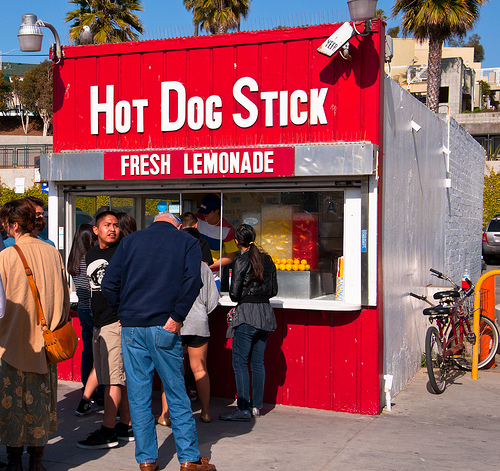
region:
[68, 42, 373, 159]
name of the resturant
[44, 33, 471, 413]
a mobile restaurant on road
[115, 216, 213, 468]
a tall person standing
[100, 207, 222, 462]
a tall person holding his hands on back pocket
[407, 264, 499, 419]
a nice by cycle parked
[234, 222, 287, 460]
a young girl standing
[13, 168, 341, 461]
a group of people standing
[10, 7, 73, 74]
a small top light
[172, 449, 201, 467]
shoe of the person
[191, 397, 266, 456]
shadow of the person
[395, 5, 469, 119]
tall green palm tree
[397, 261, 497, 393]
red bicycle built for two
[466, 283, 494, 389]
yellow pole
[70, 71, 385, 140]
hot dog stick sign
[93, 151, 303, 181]
red and white fresh lemonade sign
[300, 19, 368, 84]
security camera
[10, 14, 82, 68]
light fixture on building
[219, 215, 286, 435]
woman with a ponytail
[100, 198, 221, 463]
man in a dark blue jacket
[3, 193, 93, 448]
woman wearing a shoulder bag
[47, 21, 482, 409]
a take out restaurant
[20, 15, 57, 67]
an overhead light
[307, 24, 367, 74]
a white security camera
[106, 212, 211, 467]
a man reaching into pocket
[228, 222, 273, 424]
a woman standing on sidewalk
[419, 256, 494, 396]
a parked red bicycle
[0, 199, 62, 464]
a woman standing on sidewalk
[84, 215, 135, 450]
a man standing on sidewalk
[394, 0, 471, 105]
a large palm tree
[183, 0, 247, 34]
a large palm tree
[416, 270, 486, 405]
two person bike next to building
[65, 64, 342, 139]
name on top of building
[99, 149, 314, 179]
sign hanging on the building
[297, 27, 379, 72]
security camera on building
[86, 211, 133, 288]
boy looking at others in line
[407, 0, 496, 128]
palm tree behind building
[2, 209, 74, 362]
lady with bun in hair and satchel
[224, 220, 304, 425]
girl with ponytail and leather jacket on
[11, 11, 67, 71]
street light hanging up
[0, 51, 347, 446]
people in line for hot dog stand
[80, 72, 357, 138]
large white sign on the building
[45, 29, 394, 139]
red color on front of stand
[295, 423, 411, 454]
gray color on the ground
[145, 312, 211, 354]
man's hand in his back pocket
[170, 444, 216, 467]
man wearing brown shoes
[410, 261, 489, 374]
bike parked at the side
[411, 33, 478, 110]
large pink house on the hill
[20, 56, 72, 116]
large green cultivated tree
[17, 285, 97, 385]
brown bag around woman's shoulders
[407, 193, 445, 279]
shiny paint on white wall